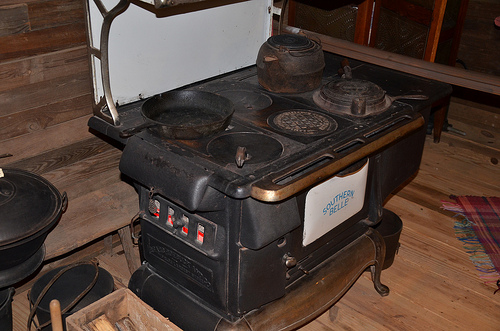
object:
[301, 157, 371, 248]
words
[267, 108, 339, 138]
burners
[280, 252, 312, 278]
control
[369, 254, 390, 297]
feet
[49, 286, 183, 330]
container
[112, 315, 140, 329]
firewood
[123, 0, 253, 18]
rack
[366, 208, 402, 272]
bucket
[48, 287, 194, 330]
bench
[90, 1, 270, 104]
screen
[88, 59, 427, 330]
stove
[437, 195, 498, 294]
rug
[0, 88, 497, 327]
floor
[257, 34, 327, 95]
tea kettle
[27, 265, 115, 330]
pot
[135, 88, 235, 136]
frying pan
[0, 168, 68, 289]
container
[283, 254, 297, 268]
knob